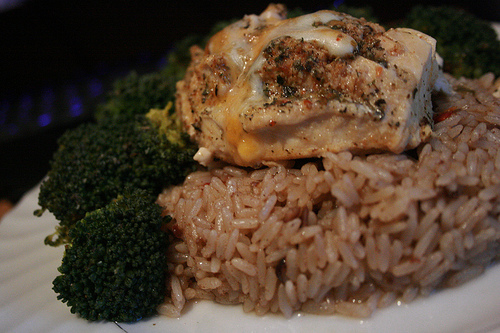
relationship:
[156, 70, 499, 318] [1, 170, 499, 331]
rice on plate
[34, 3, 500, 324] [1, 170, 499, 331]
broccoli on plate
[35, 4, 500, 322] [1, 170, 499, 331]
food on plate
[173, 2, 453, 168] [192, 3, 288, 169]
chicken has a small bone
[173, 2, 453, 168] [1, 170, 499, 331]
chicken on plate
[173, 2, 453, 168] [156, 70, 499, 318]
chicken on rice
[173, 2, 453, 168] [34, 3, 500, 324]
chicken and broccoli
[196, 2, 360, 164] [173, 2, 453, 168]
cheese on chicken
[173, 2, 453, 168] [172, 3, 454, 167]
chicken seasoned with herbs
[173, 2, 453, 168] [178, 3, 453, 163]
chicken has toppings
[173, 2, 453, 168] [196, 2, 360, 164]
chicken has cheese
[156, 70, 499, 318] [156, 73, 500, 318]
rice in a pile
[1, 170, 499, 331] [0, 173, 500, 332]
plate made of glass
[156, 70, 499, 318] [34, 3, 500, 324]
rice next to broccoli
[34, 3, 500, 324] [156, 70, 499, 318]
broccoli near rice